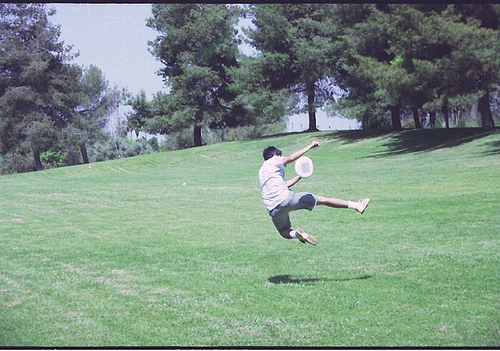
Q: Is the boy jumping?
A: Yes, the boy is jumping.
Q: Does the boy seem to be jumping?
A: Yes, the boy is jumping.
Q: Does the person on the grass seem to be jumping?
A: Yes, the boy is jumping.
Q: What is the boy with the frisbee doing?
A: The boy is jumping.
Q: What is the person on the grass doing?
A: The boy is jumping.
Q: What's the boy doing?
A: The boy is jumping.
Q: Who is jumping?
A: The boy is jumping.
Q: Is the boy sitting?
A: No, the boy is jumping.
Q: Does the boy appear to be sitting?
A: No, the boy is jumping.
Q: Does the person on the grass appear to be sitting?
A: No, the boy is jumping.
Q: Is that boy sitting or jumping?
A: The boy is jumping.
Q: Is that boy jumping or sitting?
A: The boy is jumping.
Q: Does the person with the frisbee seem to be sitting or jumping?
A: The boy is jumping.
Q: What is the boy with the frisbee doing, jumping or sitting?
A: The boy is jumping.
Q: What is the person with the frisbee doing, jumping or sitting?
A: The boy is jumping.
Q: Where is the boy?
A: The boy is in the grass.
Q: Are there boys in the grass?
A: Yes, there is a boy in the grass.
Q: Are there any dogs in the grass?
A: No, there is a boy in the grass.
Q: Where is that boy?
A: The boy is on the grass.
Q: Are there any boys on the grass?
A: Yes, there is a boy on the grass.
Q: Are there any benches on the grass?
A: No, there is a boy on the grass.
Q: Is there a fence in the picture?
A: No, there are no fences.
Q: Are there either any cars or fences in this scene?
A: No, there are no fences or cars.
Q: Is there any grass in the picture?
A: Yes, there is grass.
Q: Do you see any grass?
A: Yes, there is grass.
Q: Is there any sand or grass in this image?
A: Yes, there is grass.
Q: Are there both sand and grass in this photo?
A: No, there is grass but no sand.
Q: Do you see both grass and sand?
A: No, there is grass but no sand.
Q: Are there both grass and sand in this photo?
A: No, there is grass but no sand.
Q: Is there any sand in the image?
A: No, there is no sand.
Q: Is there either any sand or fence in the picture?
A: No, there are no sand or fences.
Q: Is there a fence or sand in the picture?
A: No, there are no sand or fences.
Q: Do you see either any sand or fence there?
A: No, there are no sand or fences.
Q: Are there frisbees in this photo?
A: Yes, there is a frisbee.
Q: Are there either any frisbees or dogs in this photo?
A: Yes, there is a frisbee.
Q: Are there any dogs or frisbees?
A: Yes, there is a frisbee.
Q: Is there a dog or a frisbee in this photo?
A: Yes, there is a frisbee.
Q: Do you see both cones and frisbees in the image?
A: No, there is a frisbee but no cones.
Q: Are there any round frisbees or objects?
A: Yes, there is a round frisbee.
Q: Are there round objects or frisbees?
A: Yes, there is a round frisbee.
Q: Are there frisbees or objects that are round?
A: Yes, the frisbee is round.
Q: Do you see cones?
A: No, there are no cones.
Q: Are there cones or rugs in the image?
A: No, there are no cones or rugs.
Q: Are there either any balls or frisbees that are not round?
A: No, there is a frisbee but it is round.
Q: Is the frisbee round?
A: Yes, the frisbee is round.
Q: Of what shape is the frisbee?
A: The frisbee is round.